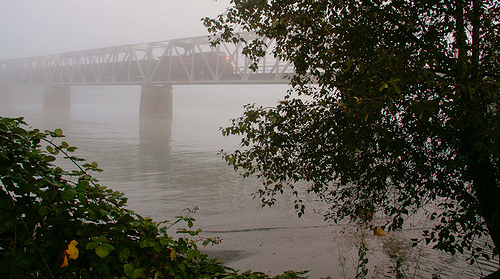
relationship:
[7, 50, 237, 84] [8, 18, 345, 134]
train on bridge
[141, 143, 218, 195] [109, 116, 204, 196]
waves in water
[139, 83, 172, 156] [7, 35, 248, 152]
pylon holding up bridge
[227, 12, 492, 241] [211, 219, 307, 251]
tree near bank